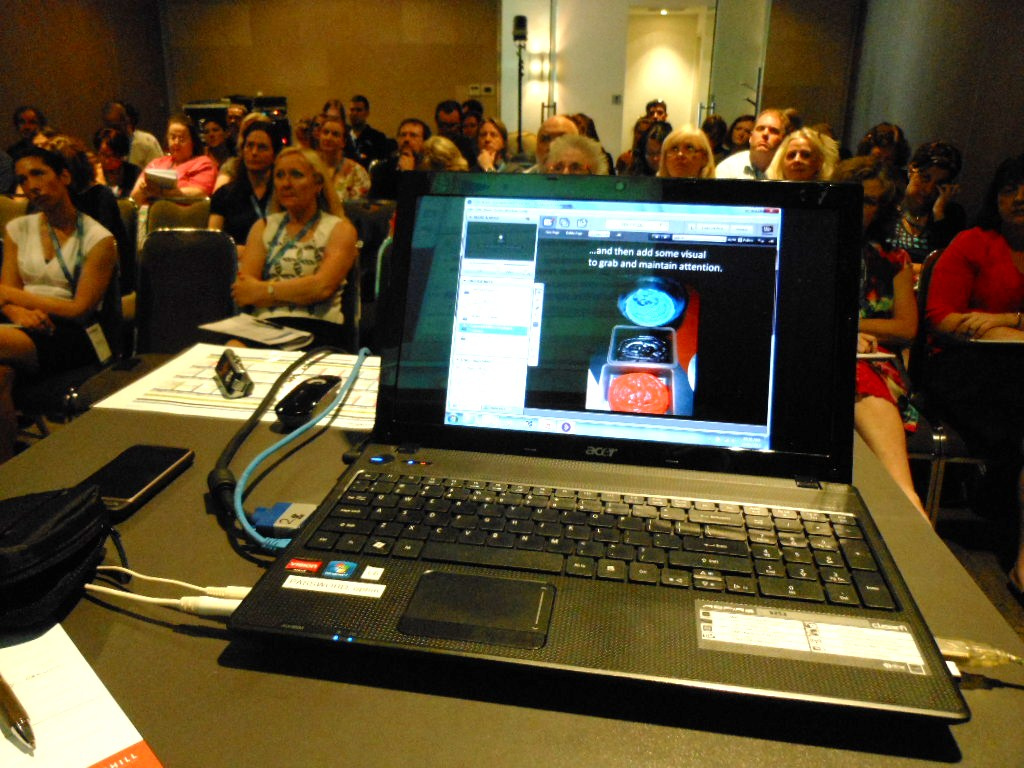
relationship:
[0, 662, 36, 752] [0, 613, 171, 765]
pen on top of paper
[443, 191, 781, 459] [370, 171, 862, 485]
computer program on black computer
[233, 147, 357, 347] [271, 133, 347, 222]
woman has hair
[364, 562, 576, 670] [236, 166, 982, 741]
black touchpad on laptop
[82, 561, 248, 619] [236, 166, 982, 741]
cord in laptop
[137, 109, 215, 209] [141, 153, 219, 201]
woman wearing shirt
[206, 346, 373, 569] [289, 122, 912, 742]
cord in laptop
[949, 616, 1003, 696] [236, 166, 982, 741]
cable connected into laptop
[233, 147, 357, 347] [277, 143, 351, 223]
woman with hair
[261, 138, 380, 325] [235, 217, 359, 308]
woman has her arms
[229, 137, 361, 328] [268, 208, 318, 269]
woman wearing lanyard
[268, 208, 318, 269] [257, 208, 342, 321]
lanyard and shirt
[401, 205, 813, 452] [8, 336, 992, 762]
black computer on table